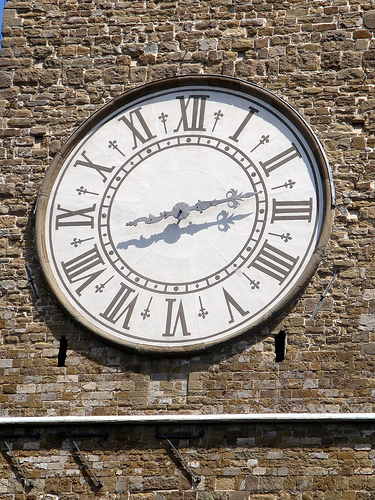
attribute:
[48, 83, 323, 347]
face — clock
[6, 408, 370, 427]
ledge — white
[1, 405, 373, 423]
shelf — pictured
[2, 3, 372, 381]
photo — detailed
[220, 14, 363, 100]
brick — greenish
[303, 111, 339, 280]
bracket — metal, around clock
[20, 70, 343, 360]
clock — large, approximately 8:12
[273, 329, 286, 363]
spot — dark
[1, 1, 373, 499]
wall — brick, stone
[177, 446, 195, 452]
brick — pictured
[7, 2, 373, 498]
building part — pictured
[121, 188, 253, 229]
hand — grey, clock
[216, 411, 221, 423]
board — pictured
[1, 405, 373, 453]
shelf — pictured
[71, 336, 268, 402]
bricks — tan-colored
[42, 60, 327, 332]
clock — large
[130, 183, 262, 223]
hand — black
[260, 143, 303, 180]
numeral — roman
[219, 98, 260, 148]
numeral — roman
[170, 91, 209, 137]
numeral — roman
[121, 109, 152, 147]
numeral — roman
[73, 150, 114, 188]
numeral — roman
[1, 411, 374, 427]
ledge — cement